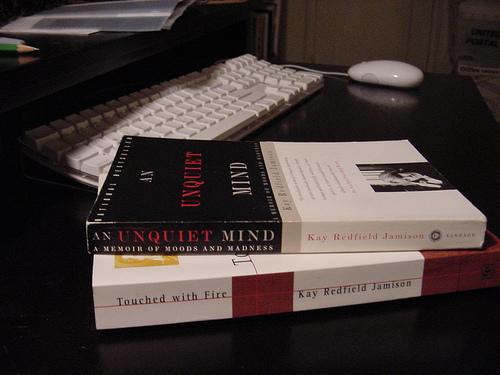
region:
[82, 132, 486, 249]
a paperback book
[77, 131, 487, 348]
a stack of paperback books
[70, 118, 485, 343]
two paperback books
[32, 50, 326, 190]
a white computer keyboard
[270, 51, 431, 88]
a mouse connected by wire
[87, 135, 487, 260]
a black, white and grey book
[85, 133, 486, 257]
a book with white and red lettering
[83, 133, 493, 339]
two books by Kay Jamison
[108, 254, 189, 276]
a yellow mark on the bottom book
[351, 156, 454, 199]
a photo of the book's author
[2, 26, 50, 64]
green wooden pencil with lead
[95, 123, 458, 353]
two book stacked on desk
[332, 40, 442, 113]
white mouse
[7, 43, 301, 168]
white computer keyboard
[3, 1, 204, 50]
stack of papers laying on desk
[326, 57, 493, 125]
shining brown desktop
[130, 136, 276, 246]
red and black book cover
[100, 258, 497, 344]
red and white book cover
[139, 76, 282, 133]
white buttons on desktop keyboard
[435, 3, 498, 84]
storage containers stacked against wall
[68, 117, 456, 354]
Two books laying on a desk.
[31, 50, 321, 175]
computer keyboard on top of a dark colored desk.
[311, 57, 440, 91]
White mouse laying on a desk.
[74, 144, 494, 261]
The book titled "An Unquiet Mind" by Kay Redfield Jamison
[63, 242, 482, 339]
The book titled "Touched by Fire" by Kay Redfield Jamison.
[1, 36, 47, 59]
The pointed end of a pencil.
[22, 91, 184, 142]
A shadow on the keyboard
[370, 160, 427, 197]
A black and white picture of a woman.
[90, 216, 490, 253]
The spine of a book.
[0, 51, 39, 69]
The reflection of a pencil.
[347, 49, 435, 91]
shiny white computer mouse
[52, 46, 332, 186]
white computer keyboard on desk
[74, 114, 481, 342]
two soft cover books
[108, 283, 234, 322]
title of book on desk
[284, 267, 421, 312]
author's name on book spine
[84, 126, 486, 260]
book on top of second book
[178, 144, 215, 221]
red word on top book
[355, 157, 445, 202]
photo of person on book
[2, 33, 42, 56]
green pencil above keyboard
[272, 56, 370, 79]
wire attached to mouse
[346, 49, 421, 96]
a white computer mouse on the table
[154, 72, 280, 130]
button on computer keboard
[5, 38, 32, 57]
a sharpened green pencil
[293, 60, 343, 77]
a gray cord connected to the mouse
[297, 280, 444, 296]
an author's name on a book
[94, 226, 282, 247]
a title on a book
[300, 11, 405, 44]
a brown wall in the background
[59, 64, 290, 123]
a white keyboard on the table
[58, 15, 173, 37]
papers lying on the edge of the desk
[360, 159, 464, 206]
a photo of a woman